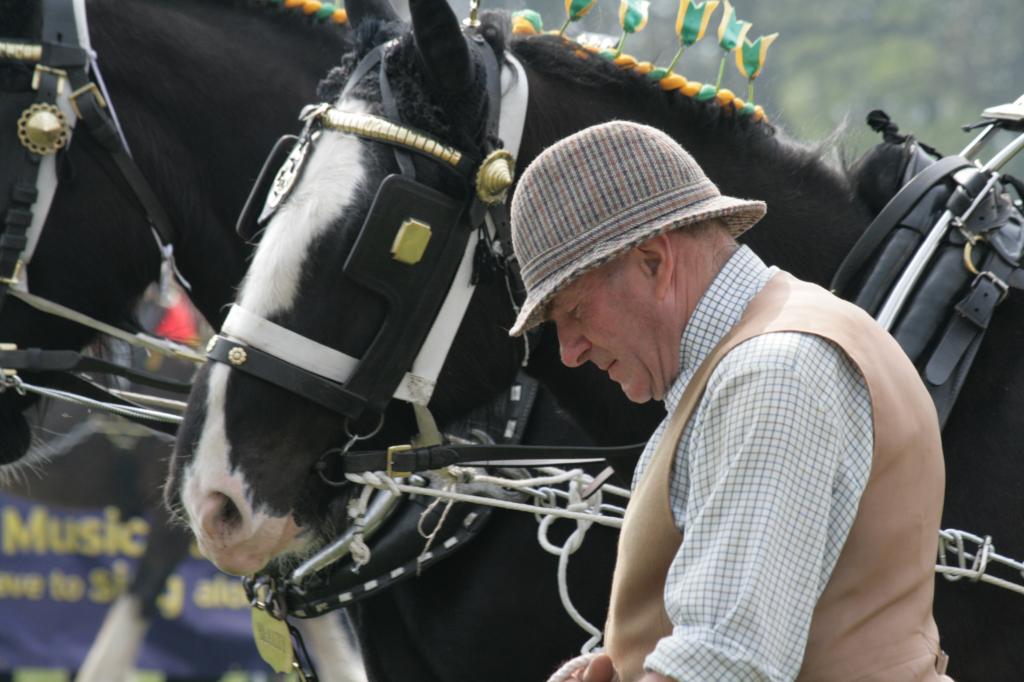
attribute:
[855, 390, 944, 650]
vest — brown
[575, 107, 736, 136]
mane — green and yellow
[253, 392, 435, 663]
mouth bit — metal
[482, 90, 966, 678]
man — older, looking down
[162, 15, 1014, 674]
horse — black, large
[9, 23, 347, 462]
horse — black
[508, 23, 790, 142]
mane — decorated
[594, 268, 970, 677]
vest — tan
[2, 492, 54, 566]
letter — yellow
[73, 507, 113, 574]
letter — yellow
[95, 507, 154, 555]
letter — yellow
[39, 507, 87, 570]
letter — yellow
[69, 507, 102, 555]
letter — yellow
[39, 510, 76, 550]
letter — yellow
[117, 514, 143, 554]
letter — yellow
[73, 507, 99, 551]
letter — yellow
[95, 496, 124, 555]
letter — yellow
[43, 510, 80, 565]
letter — yellow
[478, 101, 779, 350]
hat — bucket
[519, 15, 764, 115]
ribon — green, orange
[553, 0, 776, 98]
flags — green, orange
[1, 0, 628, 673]
horse — large, black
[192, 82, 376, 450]
mark — white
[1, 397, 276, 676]
banner — purple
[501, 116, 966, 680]
outfit — brown, white